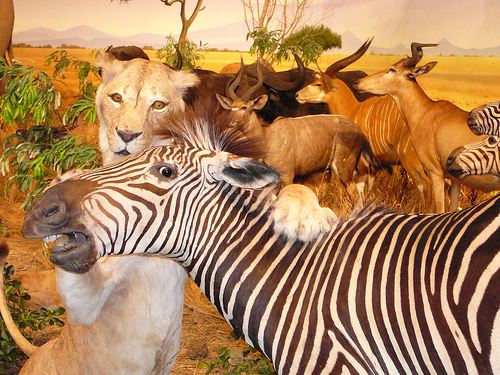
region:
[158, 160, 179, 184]
zebra with black eyes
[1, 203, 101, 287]
zebra with its mouth opened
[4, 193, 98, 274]
zebra with a black nose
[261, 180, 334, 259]
lion paw on a zebra back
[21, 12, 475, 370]
Animals in the jungle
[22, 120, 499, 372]
white and black zebra in museum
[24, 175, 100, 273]
black open mouth of zebra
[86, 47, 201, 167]
lion head above zebra head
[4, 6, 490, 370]
bush scene depicted in Africa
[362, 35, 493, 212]
brown antelope with antlers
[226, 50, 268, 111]
long curved grey antlers on antelope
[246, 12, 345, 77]
green trees growing in bush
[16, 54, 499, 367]
lion depicted attacking zebra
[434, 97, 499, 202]
two zebra noses and heads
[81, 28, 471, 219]
herd of brown and grey antelope in the background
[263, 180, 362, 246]
white mound on back of zebra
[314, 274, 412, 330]
black and white stripes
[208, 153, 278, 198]
ears on zebra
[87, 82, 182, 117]
lion's beautiful yellow eyes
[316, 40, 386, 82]
horns on top of animal's head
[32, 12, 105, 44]
tall mountain range in the horizon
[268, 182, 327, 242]
paw on back on zebra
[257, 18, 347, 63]
small green tree on the vista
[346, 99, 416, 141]
white stripes on animal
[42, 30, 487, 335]
animals in the desert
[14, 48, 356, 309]
lion on a zebra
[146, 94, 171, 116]
lion with brown eyes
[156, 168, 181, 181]
zebra with black eyes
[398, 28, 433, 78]
horns on a gazelle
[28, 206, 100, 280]
zebra with its mouth opened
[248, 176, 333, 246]
lion paw on zebras back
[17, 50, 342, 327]
lion attacking a zebra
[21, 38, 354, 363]
lion jumping on a zebra